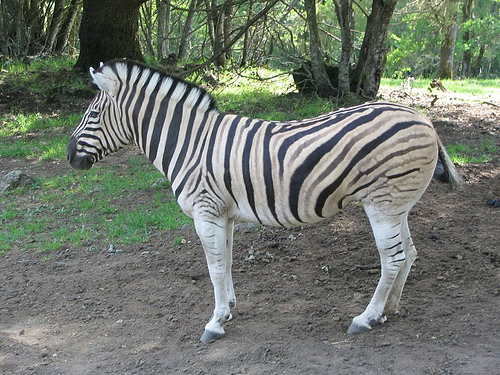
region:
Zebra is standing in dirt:
[57, 47, 454, 344]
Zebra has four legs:
[177, 166, 414, 363]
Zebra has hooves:
[202, 292, 397, 359]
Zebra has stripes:
[69, 60, 480, 306]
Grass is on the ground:
[12, 162, 184, 256]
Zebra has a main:
[74, 48, 229, 128]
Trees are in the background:
[22, 7, 479, 77]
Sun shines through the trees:
[192, 25, 499, 95]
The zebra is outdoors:
[18, 24, 487, 341]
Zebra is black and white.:
[57, 54, 457, 318]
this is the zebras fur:
[160, 110, 372, 203]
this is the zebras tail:
[434, 135, 476, 195]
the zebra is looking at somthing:
[51, 10, 174, 250]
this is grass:
[113, 209, 158, 236]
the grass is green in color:
[302, 95, 320, 112]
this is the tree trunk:
[75, 0, 145, 58]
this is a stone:
[0, 168, 34, 205]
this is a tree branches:
[178, 5, 299, 87]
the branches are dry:
[185, 9, 285, 74]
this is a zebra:
[56, 54, 468, 340]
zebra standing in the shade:
[189, 130, 498, 292]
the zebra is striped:
[100, 85, 385, 220]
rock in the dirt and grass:
[0, 160, 55, 205]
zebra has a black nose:
[55, 125, 110, 165]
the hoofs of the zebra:
[190, 305, 425, 360]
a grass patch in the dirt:
[43, 179, 167, 234]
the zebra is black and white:
[109, 86, 338, 208]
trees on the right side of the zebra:
[186, 15, 487, 75]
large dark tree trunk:
[62, 15, 177, 60]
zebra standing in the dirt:
[97, 136, 499, 325]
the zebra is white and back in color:
[55, 62, 462, 342]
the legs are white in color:
[195, 223, 232, 328]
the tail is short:
[441, 148, 463, 193]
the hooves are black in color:
[198, 326, 223, 336]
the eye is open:
[86, 106, 101, 118]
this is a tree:
[303, 2, 390, 92]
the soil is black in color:
[245, 242, 351, 358]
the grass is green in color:
[51, 172, 131, 212]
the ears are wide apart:
[88, 62, 121, 93]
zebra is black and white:
[50, 57, 488, 261]